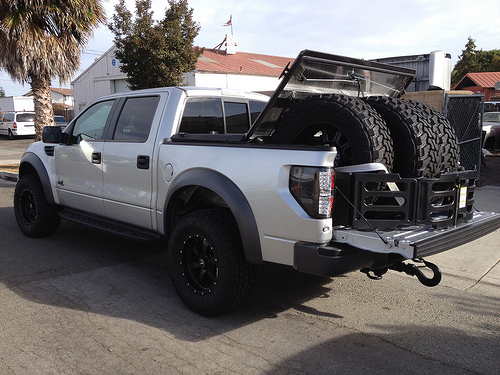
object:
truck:
[13, 48, 499, 318]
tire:
[270, 92, 395, 225]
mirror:
[43, 126, 63, 143]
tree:
[0, 0, 108, 143]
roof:
[192, 45, 299, 77]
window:
[178, 96, 267, 134]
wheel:
[360, 95, 460, 204]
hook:
[411, 257, 442, 288]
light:
[292, 176, 314, 201]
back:
[230, 93, 500, 288]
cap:
[164, 164, 172, 182]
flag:
[221, 19, 232, 27]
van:
[0, 111, 37, 141]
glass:
[179, 98, 225, 135]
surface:
[52, 264, 135, 337]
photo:
[0, 0, 500, 375]